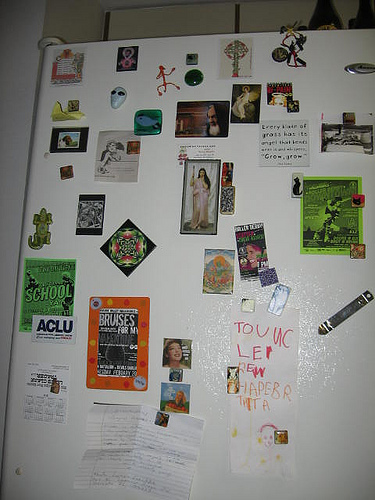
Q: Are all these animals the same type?
A: No, there are both lizards and cats.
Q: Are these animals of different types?
A: Yes, they are lizards and cats.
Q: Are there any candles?
A: No, there are no candles.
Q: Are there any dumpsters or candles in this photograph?
A: No, there are no candles or dumpsters.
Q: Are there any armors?
A: No, there are no armors.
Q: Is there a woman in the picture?
A: Yes, there is a woman.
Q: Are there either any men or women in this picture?
A: Yes, there is a woman.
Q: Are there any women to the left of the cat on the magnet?
A: Yes, there is a woman to the left of the cat.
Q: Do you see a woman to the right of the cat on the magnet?
A: No, the woman is to the left of the cat.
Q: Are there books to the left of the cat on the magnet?
A: No, there is a woman to the left of the cat.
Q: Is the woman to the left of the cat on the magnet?
A: Yes, the woman is to the left of the cat.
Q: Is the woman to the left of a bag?
A: No, the woman is to the left of the cat.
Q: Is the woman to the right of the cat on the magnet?
A: No, the woman is to the left of the cat.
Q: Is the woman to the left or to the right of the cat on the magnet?
A: The woman is to the left of the cat.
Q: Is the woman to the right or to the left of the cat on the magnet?
A: The woman is to the left of the cat.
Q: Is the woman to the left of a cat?
A: Yes, the woman is to the left of a cat.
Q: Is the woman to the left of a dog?
A: No, the woman is to the left of a cat.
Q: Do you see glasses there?
A: No, there are no glasses.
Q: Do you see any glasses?
A: No, there are no glasses.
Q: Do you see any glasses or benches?
A: No, there are no glasses or benches.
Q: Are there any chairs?
A: No, there are no chairs.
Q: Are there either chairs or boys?
A: No, there are no chairs or boys.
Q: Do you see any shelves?
A: No, there are no shelves.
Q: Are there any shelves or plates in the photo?
A: No, there are no shelves or plates.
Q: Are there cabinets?
A: No, there are no cabinets.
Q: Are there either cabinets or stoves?
A: No, there are no cabinets or stoves.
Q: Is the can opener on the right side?
A: Yes, the can opener is on the right of the image.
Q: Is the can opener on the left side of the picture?
A: No, the can opener is on the right of the image.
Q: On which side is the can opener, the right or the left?
A: The can opener is on the right of the image.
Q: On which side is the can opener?
A: The can opener is on the right of the image.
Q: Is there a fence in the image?
A: No, there are no fences.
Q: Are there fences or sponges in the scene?
A: No, there are no fences or sponges.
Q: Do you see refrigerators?
A: Yes, there is a refrigerator.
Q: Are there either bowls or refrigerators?
A: Yes, there is a refrigerator.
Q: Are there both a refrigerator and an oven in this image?
A: No, there is a refrigerator but no ovens.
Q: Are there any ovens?
A: No, there are no ovens.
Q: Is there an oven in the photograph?
A: No, there are no ovens.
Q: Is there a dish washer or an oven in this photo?
A: No, there are no ovens or dishwashers.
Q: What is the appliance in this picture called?
A: The appliance is a refrigerator.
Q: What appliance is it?
A: The appliance is a refrigerator.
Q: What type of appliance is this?
A: That is a refrigerator.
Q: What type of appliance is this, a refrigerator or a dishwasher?
A: That is a refrigerator.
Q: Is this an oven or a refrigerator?
A: This is a refrigerator.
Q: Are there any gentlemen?
A: No, there are no gentlemen.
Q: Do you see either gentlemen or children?
A: No, there are no gentlemen or children.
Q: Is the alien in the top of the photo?
A: Yes, the alien is in the top of the image.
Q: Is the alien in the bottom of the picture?
A: No, the alien is in the top of the image.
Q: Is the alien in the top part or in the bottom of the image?
A: The alien is in the top of the image.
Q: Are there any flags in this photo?
A: No, there are no flags.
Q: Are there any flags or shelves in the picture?
A: No, there are no flags or shelves.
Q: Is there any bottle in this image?
A: Yes, there is a bottle.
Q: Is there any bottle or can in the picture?
A: Yes, there is a bottle.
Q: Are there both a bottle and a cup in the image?
A: No, there is a bottle but no cups.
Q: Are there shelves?
A: No, there are no shelves.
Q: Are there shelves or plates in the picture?
A: No, there are no shelves or plates.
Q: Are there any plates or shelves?
A: No, there are no shelves or plates.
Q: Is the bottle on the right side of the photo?
A: Yes, the bottle is on the right of the image.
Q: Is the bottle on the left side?
A: No, the bottle is on the right of the image.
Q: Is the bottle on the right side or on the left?
A: The bottle is on the right of the image.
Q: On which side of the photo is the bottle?
A: The bottle is on the right of the image.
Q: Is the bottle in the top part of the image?
A: Yes, the bottle is in the top of the image.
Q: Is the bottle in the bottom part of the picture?
A: No, the bottle is in the top of the image.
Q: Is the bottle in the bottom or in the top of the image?
A: The bottle is in the top of the image.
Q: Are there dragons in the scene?
A: No, there are no dragons.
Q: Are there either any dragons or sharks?
A: No, there are no dragons or sharks.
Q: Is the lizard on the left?
A: Yes, the lizard is on the left of the image.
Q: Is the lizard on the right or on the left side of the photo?
A: The lizard is on the left of the image.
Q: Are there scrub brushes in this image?
A: No, there are no scrub brushes.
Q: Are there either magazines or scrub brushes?
A: No, there are no scrub brushes or magazines.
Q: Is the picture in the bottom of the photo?
A: Yes, the picture is in the bottom of the image.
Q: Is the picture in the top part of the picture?
A: No, the picture is in the bottom of the image.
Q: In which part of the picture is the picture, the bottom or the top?
A: The picture is in the bottom of the image.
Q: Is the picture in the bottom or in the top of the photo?
A: The picture is in the bottom of the image.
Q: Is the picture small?
A: Yes, the picture is small.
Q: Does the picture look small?
A: Yes, the picture is small.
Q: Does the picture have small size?
A: Yes, the picture is small.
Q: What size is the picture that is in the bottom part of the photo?
A: The picture is small.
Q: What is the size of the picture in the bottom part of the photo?
A: The picture is small.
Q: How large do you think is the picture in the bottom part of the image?
A: The picture is small.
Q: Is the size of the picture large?
A: No, the picture is small.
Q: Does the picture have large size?
A: No, the picture is small.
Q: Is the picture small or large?
A: The picture is small.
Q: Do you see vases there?
A: No, there are no vases.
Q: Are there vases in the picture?
A: No, there are no vases.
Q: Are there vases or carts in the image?
A: No, there are no vases or carts.